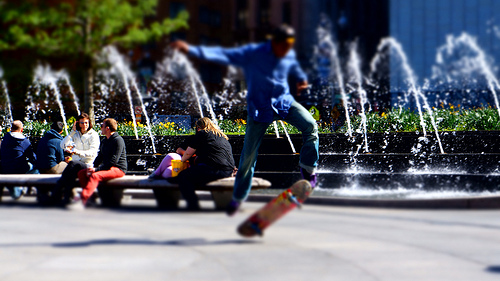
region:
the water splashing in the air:
[0, 13, 499, 197]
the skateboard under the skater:
[236, 179, 311, 236]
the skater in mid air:
[168, 23, 318, 216]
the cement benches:
[2, 173, 271, 210]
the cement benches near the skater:
[0, 173, 270, 209]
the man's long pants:
[79, 165, 124, 203]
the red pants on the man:
[77, 165, 124, 202]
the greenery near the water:
[0, 100, 498, 139]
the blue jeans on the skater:
[230, 99, 318, 203]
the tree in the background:
[0, 0, 187, 125]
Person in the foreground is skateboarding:
[161, 12, 350, 249]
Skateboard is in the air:
[229, 174, 326, 249]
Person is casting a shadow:
[23, 222, 267, 264]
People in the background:
[2, 106, 237, 221]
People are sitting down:
[1, 109, 242, 219]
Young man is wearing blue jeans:
[224, 93, 329, 208]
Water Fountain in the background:
[1, 28, 498, 165]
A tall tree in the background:
[2, 2, 197, 123]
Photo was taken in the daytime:
[1, 3, 497, 274]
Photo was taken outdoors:
[3, 4, 492, 279]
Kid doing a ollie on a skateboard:
[183, 23, 330, 243]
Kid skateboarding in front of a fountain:
[190, 16, 350, 240]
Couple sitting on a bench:
[61, 108, 128, 225]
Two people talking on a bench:
[55, 108, 127, 218]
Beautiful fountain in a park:
[21, 43, 499, 159]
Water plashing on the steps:
[321, 119, 499, 199]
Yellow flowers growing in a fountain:
[122, 102, 485, 134]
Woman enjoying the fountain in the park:
[182, 115, 240, 212]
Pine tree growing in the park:
[0, 6, 177, 53]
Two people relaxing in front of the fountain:
[49, 103, 126, 208]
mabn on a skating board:
[233, 29, 345, 236]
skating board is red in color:
[236, 190, 319, 235]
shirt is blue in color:
[243, 37, 301, 109]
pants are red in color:
[88, 162, 108, 192]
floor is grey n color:
[300, 217, 435, 275]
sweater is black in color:
[110, 128, 130, 158]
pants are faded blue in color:
[258, 111, 314, 192]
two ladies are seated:
[63, 119, 133, 178]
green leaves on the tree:
[63, 20, 84, 40]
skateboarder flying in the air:
[174, 25, 317, 236]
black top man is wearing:
[92, 132, 127, 173]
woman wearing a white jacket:
[52, 112, 101, 205]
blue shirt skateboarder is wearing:
[186, 38, 307, 115]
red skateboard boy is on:
[236, 179, 317, 237]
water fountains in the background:
[0, 32, 498, 181]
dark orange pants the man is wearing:
[78, 166, 124, 198]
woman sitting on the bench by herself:
[179, 116, 235, 213]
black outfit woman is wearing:
[168, 131, 235, 206]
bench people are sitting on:
[0, 160, 270, 215]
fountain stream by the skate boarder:
[22, 68, 71, 140]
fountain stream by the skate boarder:
[85, 40, 135, 135]